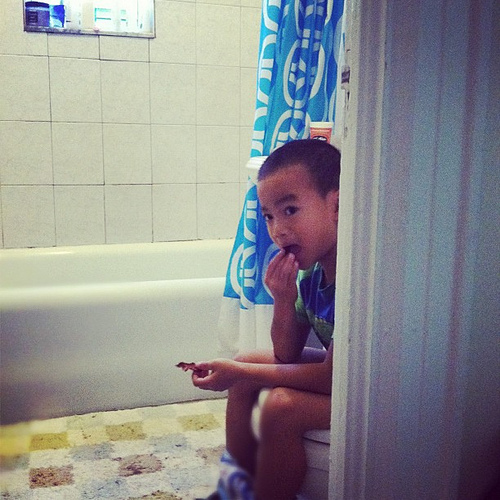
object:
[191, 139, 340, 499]
boy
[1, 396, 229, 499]
rug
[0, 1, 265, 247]
wall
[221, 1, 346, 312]
curtain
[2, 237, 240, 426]
tub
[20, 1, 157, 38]
window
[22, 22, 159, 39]
ledge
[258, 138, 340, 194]
hair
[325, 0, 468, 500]
frame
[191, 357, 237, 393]
hand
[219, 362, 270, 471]
leg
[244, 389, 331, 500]
leg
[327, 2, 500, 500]
door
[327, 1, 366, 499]
edge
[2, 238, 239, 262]
edge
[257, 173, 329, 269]
face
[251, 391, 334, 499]
toilet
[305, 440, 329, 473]
edge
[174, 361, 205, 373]
snack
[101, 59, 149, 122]
tile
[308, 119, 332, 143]
cup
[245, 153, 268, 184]
sink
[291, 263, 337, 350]
shirt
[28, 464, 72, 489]
square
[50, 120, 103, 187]
tile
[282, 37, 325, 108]
circle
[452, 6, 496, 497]
wall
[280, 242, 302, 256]
mouth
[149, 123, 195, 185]
tile